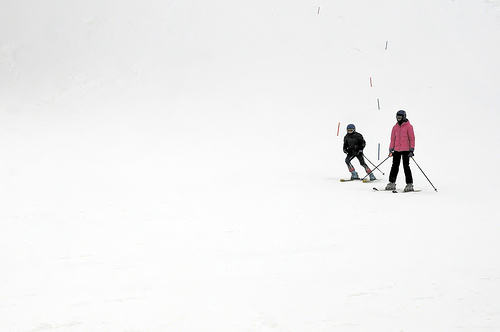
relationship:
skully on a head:
[396, 110, 405, 120] [395, 110, 406, 122]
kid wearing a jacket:
[384, 110, 415, 191] [389, 119, 414, 152]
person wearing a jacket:
[342, 124, 375, 180] [343, 132, 366, 153]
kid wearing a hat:
[384, 110, 415, 191] [396, 110, 405, 120]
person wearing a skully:
[342, 124, 375, 180] [347, 125, 355, 132]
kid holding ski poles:
[384, 110, 415, 191] [361, 152, 438, 192]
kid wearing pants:
[384, 110, 415, 191] [388, 151, 413, 182]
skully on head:
[396, 110, 405, 120] [395, 110, 406, 122]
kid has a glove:
[384, 110, 415, 191] [389, 151, 393, 156]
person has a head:
[342, 124, 375, 180] [346, 124, 355, 135]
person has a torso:
[342, 124, 375, 180] [348, 147, 362, 155]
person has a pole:
[342, 124, 375, 180] [362, 154, 385, 174]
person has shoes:
[342, 124, 375, 180] [350, 171, 375, 180]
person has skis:
[342, 124, 375, 180] [339, 178, 377, 183]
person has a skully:
[342, 124, 375, 180] [347, 125, 355, 132]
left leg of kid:
[358, 155, 375, 180] [383, 106, 417, 188]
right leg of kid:
[345, 154, 357, 175] [381, 107, 418, 186]